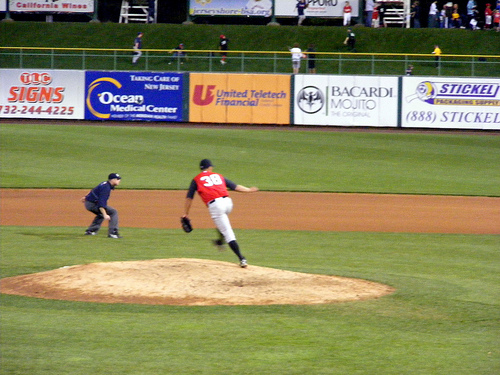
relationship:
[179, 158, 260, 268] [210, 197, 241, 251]
baseball player wearing pants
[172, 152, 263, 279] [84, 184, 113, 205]
baseball player wearing shirt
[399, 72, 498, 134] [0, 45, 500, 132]
sign posted along fence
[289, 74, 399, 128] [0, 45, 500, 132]
poster posted along fence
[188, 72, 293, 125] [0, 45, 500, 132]
sign posted along fence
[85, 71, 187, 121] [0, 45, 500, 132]
sign posted along fence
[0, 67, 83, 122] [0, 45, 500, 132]
sign posted along fence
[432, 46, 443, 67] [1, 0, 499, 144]
man in background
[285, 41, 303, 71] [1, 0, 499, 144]
people in background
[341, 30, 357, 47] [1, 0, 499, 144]
people in background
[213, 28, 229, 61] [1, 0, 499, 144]
people in background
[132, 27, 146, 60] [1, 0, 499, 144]
people in background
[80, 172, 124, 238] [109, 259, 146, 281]
player standing near base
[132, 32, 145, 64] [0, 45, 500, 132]
people playing outside fence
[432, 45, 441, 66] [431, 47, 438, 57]
man wearing jacket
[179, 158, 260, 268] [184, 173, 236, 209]
baseball player wearing jersey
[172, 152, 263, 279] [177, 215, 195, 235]
baseball player holding catcher glove